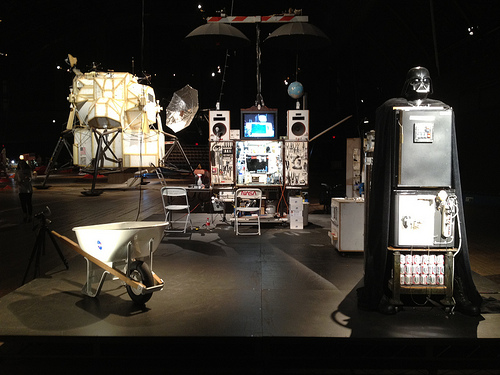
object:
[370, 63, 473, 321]
robot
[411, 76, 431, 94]
mask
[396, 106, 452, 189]
boxes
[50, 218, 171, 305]
wheelbarrow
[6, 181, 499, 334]
floor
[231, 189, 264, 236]
chair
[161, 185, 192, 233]
chair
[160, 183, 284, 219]
table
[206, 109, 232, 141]
boxes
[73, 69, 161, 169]
structure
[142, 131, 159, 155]
panels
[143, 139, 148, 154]
strips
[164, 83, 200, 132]
umbrella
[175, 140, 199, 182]
stand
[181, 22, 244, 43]
umbrella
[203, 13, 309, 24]
bar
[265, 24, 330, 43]
umbrella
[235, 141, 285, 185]
box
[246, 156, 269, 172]
opening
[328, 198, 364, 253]
cabinet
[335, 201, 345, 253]
wood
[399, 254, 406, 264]
cans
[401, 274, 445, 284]
row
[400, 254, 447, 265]
row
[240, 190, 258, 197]
graffiti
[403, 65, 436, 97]
head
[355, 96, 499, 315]
cape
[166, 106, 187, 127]
light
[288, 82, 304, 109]
globe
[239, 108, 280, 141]
television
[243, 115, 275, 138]
screen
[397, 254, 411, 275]
compartment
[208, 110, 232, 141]
speaker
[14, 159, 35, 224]
lady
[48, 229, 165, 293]
handles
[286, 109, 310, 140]
speaker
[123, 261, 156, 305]
tire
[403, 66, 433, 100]
character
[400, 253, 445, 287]
stack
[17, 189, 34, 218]
pants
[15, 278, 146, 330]
shadow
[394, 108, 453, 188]
box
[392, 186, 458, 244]
box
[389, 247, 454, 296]
box